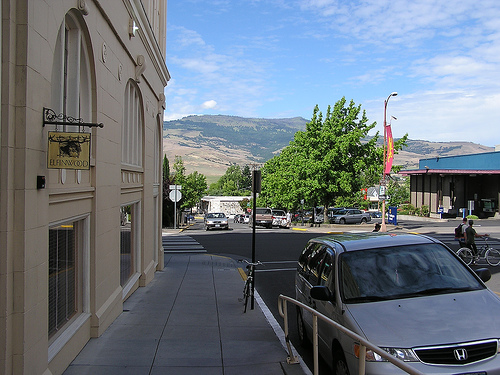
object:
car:
[293, 230, 498, 368]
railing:
[276, 293, 424, 374]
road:
[160, 231, 499, 369]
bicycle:
[237, 258, 264, 312]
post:
[251, 170, 262, 309]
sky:
[170, 1, 500, 147]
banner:
[385, 125, 394, 174]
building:
[1, 4, 171, 374]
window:
[48, 219, 84, 340]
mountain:
[163, 114, 497, 185]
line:
[164, 250, 207, 253]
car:
[204, 212, 230, 231]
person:
[465, 219, 488, 257]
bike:
[455, 234, 500, 266]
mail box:
[388, 206, 399, 225]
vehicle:
[272, 210, 288, 229]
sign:
[169, 189, 182, 202]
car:
[330, 208, 371, 224]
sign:
[47, 131, 91, 172]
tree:
[244, 96, 406, 211]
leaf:
[339, 122, 342, 126]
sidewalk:
[63, 254, 308, 373]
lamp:
[386, 92, 399, 104]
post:
[382, 107, 386, 232]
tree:
[247, 95, 413, 212]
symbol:
[455, 349, 466, 361]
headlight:
[354, 345, 419, 362]